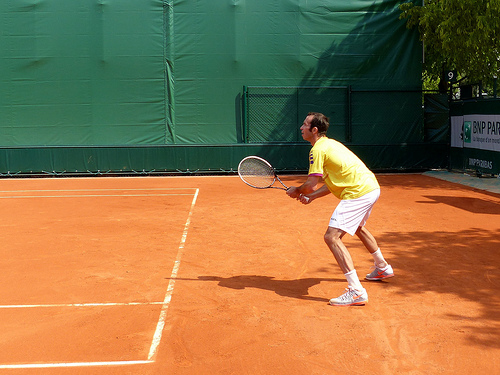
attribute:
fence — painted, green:
[237, 84, 500, 177]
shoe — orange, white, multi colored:
[317, 285, 370, 311]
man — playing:
[281, 108, 400, 308]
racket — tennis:
[233, 153, 311, 201]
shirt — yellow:
[305, 135, 383, 201]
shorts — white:
[326, 185, 383, 240]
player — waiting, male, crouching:
[229, 99, 400, 320]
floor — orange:
[1, 172, 499, 374]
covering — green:
[1, 1, 435, 176]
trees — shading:
[394, 0, 499, 97]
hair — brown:
[308, 111, 334, 136]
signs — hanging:
[449, 111, 500, 183]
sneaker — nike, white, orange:
[360, 260, 404, 288]